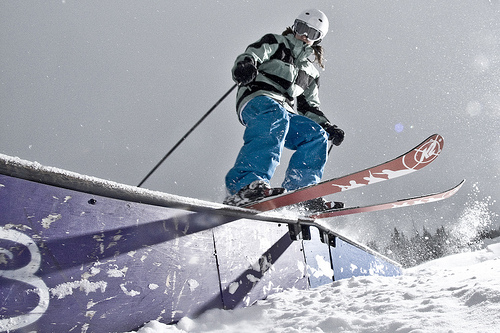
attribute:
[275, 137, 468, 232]
skiboard — red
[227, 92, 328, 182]
pants — blue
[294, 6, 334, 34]
helmet — white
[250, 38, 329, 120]
jacket — stripes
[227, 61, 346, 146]
gloves — black